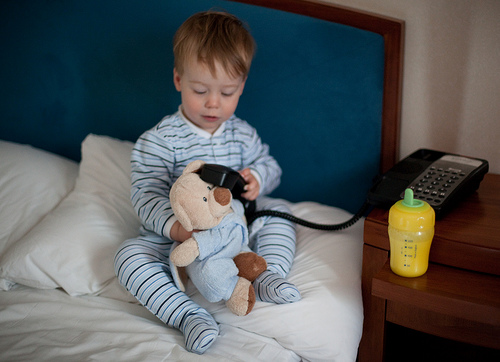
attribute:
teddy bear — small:
[163, 163, 269, 313]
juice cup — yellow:
[385, 188, 438, 282]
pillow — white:
[4, 141, 78, 255]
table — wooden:
[355, 163, 497, 359]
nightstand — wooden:
[360, 166, 499, 356]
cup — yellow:
[386, 184, 436, 274]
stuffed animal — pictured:
[167, 158, 265, 319]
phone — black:
[363, 145, 492, 217]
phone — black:
[200, 148, 489, 232]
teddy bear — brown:
[158, 154, 267, 314]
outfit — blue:
[188, 189, 245, 304]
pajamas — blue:
[115, 110, 304, 356]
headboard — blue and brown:
[257, 0, 407, 121]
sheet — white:
[3, 296, 132, 359]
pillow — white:
[2, 135, 83, 252]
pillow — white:
[0, 128, 129, 295]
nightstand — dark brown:
[356, 162, 485, 359]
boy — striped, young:
[110, 9, 316, 352]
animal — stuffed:
[170, 159, 265, 313]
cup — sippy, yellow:
[388, 189, 434, 276]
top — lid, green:
[400, 189, 420, 207]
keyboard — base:
[413, 156, 483, 212]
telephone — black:
[193, 162, 255, 223]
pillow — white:
[0, 133, 363, 360]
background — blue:
[1, 0, 140, 127]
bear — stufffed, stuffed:
[170, 158, 267, 314]